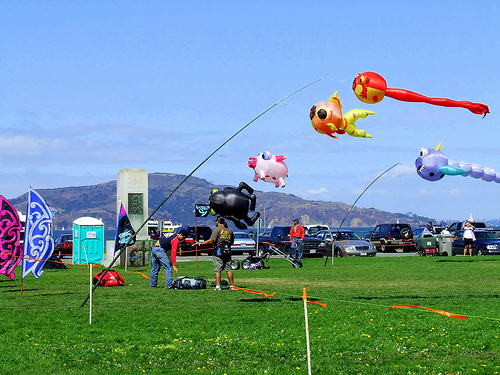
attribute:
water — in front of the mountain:
[347, 220, 367, 230]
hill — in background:
[169, 169, 206, 206]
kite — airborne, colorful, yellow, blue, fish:
[308, 92, 355, 136]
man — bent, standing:
[154, 227, 196, 272]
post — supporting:
[293, 288, 324, 354]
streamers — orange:
[403, 293, 451, 326]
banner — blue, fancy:
[375, 156, 399, 178]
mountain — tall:
[66, 180, 105, 212]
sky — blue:
[80, 23, 191, 98]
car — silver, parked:
[338, 236, 371, 255]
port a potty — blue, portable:
[71, 221, 107, 266]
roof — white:
[69, 209, 100, 230]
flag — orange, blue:
[253, 288, 271, 300]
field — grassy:
[132, 307, 259, 369]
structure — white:
[116, 164, 158, 213]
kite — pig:
[240, 141, 307, 188]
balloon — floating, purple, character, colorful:
[421, 145, 492, 190]